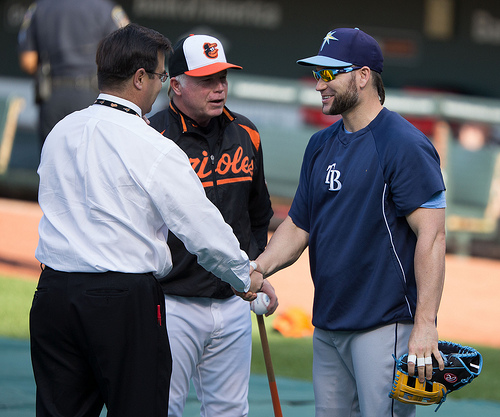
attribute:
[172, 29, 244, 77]
cap — orange, black, white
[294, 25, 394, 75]
hat — green, blue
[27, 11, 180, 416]
man — standing, white, old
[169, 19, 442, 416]
men — coaches, white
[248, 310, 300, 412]
bat — brown, long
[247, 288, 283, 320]
ball — white, round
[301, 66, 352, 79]
sunglasses — blue, yellow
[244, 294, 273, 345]
handle — brown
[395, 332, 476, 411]
glove — black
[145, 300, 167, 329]
pen — ink, red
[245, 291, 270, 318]
baseball — white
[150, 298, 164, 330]
pen — red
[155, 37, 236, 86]
hat — orange, white, black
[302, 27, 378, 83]
cap — sky blue, navy blue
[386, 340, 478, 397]
glove — blue, yellow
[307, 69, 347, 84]
sunglasses — yellow, blue